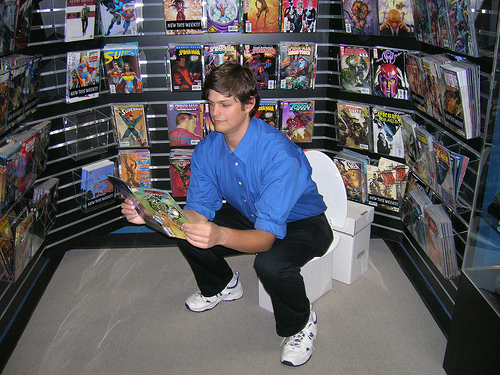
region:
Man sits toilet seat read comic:
[104, 61, 353, 373]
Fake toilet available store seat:
[247, 141, 387, 319]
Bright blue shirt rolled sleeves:
[187, 68, 325, 242]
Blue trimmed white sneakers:
[163, 266, 362, 373]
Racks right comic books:
[364, 3, 482, 247]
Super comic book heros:
[59, 43, 149, 160]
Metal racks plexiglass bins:
[42, 101, 112, 227]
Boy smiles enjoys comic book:
[202, 61, 266, 136]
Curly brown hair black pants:
[195, 59, 274, 313]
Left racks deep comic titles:
[2, 4, 61, 300]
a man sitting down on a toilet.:
[121, 59, 383, 363]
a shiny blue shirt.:
[166, 104, 346, 244]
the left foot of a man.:
[272, 309, 321, 374]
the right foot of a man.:
[178, 259, 247, 324]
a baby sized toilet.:
[249, 143, 348, 315]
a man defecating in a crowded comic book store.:
[106, 54, 377, 368]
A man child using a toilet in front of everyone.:
[121, 56, 338, 362]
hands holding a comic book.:
[119, 169, 210, 268]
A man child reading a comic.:
[119, 59, 375, 367]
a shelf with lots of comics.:
[1, 1, 498, 308]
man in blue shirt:
[134, 76, 345, 366]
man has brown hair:
[121, 45, 375, 359]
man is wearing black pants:
[137, 56, 344, 363]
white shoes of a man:
[128, 74, 334, 364]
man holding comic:
[142, 70, 417, 338]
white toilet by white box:
[246, 136, 403, 304]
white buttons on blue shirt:
[220, 134, 271, 233]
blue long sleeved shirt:
[163, 121, 360, 276]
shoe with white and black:
[280, 314, 343, 365]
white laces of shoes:
[281, 331, 306, 339]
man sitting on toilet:
[128, 50, 369, 354]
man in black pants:
[185, 123, 331, 359]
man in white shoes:
[138, 61, 335, 361]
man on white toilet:
[135, 73, 375, 373]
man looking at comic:
[100, 47, 418, 354]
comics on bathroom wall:
[25, 14, 495, 172]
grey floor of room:
[61, 230, 191, 373]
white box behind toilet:
[335, 207, 414, 299]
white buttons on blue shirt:
[214, 157, 291, 244]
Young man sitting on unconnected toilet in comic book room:
[118, 60, 334, 367]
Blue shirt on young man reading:
[180, 120, 327, 230]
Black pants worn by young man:
[175, 205, 333, 338]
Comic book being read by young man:
[102, 170, 185, 240]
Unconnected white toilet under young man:
[250, 146, 347, 312]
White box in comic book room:
[335, 196, 375, 286]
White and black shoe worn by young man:
[275, 310, 321, 368]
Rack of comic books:
[416, 198, 466, 279]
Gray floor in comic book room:
[3, 238, 445, 373]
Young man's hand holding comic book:
[180, 216, 220, 251]